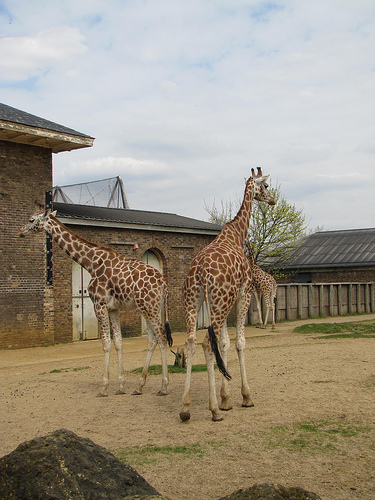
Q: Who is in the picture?
A: Giraffes.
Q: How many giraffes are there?
A: Three.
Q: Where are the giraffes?
A: Zoo.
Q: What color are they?
A: Brown and white.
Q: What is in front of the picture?
A: Rock.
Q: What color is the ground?
A: Brown.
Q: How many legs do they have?
A: Four.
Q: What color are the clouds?
A: White.